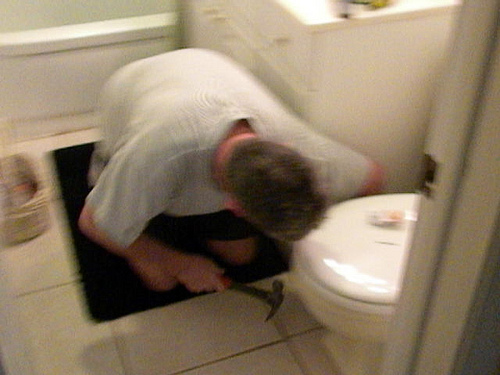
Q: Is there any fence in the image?
A: No, there are no fences.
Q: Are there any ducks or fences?
A: No, there are no fences or ducks.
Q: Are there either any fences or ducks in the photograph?
A: No, there are no fences or ducks.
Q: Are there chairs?
A: No, there are no chairs.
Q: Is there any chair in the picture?
A: No, there are no chairs.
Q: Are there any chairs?
A: No, there are no chairs.